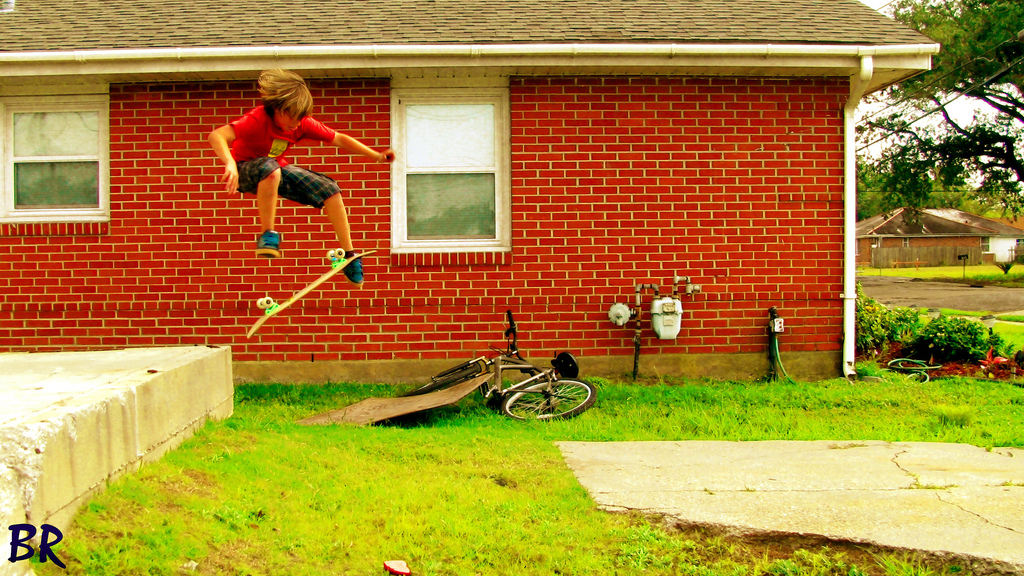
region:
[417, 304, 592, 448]
bicycle laying on the grass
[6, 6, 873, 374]
red brick house with black roof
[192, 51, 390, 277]
young boy wearing red shirt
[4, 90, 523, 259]
windows with white frames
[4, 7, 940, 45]
black shingle roof on the house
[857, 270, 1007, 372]
shrubs next to the house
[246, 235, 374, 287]
blue shoes the boy is wearing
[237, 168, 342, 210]
black shorts the boy is wearing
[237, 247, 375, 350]
skateboard with white wheels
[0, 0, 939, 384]
A home made from bricks.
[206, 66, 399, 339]
A child performing a skateboard trick.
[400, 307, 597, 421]
A bike laying on its side.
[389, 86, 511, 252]
the window has a white frame.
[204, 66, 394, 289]
The child is wearing a red t-shirt.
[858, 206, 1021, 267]
A wooden fence is next to a large house.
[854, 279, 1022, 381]
small and medium sized plants in mulch.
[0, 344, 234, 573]
A slightly damaged concrete slab.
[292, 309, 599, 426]
A piece of wood is on top of the bike.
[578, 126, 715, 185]
The surface of a reddish brick wall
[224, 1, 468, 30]
The tiles on the roof of a house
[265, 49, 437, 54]
A horizontal drain pipe along the roof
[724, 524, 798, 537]
The broken edge of a concrete floor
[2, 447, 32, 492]
The chipped edge of a platform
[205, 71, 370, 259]
A boy jumping in the air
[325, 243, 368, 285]
Foot of the boy touching the skate board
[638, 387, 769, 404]
A patch of green grass next to the house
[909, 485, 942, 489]
Grass growing in a crack on the slab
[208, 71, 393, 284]
Brown haired kid in the air.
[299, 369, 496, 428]
Wooden brown ramp on the ground.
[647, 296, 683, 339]
Gas meter on the building side.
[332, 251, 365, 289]
A boys left blue and black shoe.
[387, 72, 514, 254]
White framed window in front of a boy in the air.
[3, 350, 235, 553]
Worn white cement porch area.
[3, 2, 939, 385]
Red brick house with white framed windows.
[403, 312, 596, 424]
Black bicycle lying on the ground.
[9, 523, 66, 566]
The blue letters BR.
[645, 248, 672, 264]
A brick in a wall.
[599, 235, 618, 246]
A brick in a wall.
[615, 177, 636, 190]
A brick in a wall.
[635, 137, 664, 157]
A brick in a wall.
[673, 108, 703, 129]
A brick in a wall.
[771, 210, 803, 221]
A brick in a wall.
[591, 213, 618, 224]
A brick in a wall.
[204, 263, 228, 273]
A brick in a wall.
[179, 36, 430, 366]
A skateboarder in the air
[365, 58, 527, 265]
A window on the house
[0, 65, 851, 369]
Bricks on side of a house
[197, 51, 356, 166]
Boy wearing a red shirt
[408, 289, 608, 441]
A bicycle on the grass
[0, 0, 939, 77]
The roof of a house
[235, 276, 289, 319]
Wheels of a skateboard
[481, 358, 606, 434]
A black round bicycle wheel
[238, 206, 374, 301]
A pair of black sneakers